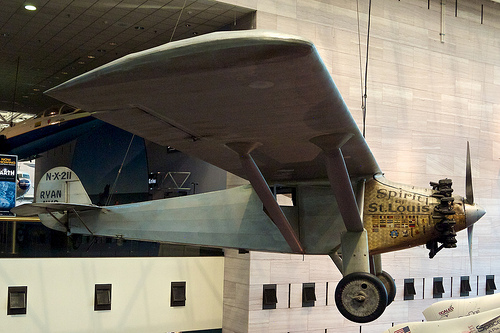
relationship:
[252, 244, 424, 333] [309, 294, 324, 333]
two wheels are visible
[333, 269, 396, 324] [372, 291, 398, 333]
two wheels are visible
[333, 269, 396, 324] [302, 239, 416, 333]
two wheels are visible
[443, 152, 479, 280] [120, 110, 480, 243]
propeller of airplane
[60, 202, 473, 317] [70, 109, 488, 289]
airplane model hanging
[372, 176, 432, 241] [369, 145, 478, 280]
spirit of st lou decal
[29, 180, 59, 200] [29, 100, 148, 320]
ryan decal on tail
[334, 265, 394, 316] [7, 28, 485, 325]
tires on airplane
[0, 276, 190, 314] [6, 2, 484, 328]
windows on building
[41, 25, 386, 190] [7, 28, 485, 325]
wing on airplane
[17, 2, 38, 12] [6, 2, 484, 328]
light in building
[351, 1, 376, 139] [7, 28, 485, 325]
cable holding airplane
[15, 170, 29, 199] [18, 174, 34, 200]
nose of airplane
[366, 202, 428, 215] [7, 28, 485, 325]
writing on airplane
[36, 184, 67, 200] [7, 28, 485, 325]
writing on airplane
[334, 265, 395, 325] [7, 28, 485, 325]
wheels on airplane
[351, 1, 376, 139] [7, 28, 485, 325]
cable attached to airplane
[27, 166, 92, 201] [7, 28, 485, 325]
fin on airplane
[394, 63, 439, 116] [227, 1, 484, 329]
tiles on wall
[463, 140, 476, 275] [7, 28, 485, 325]
propeller on airplane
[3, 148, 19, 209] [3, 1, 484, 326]
sign in museum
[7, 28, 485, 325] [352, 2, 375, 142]
airplane from cable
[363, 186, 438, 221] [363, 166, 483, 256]
name on nose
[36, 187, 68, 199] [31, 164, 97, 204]
letters on tail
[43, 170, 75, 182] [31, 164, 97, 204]
numbers on tail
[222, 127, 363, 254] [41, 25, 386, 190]
braces under wing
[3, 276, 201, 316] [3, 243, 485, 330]
squares on wall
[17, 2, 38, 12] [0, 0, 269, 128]
light in ceiling